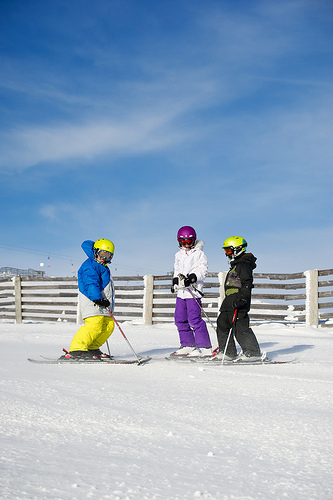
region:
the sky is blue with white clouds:
[14, 7, 332, 251]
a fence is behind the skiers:
[4, 267, 330, 329]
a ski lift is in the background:
[2, 236, 177, 291]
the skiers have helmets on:
[95, 223, 248, 258]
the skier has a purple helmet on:
[170, 224, 199, 250]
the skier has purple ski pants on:
[173, 293, 212, 347]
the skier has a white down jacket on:
[172, 244, 205, 297]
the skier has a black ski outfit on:
[220, 234, 260, 355]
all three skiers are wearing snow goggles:
[90, 235, 238, 265]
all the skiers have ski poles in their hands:
[36, 273, 267, 364]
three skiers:
[76, 230, 276, 359]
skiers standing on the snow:
[90, 233, 283, 371]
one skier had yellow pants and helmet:
[62, 238, 120, 361]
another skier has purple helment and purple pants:
[173, 222, 208, 372]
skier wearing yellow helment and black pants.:
[222, 237, 266, 343]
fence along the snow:
[29, 268, 331, 323]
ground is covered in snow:
[73, 383, 317, 491]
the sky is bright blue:
[75, 23, 295, 142]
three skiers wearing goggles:
[91, 234, 244, 261]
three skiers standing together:
[86, 220, 273, 370]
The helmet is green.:
[216, 232, 258, 260]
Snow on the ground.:
[177, 431, 237, 467]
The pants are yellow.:
[65, 314, 119, 356]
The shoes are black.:
[54, 341, 118, 365]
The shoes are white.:
[174, 342, 211, 359]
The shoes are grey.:
[210, 341, 272, 370]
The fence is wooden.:
[265, 276, 307, 312]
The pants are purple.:
[164, 298, 215, 346]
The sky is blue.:
[6, 16, 63, 46]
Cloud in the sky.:
[32, 132, 94, 161]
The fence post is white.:
[129, 276, 158, 321]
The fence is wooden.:
[27, 286, 54, 310]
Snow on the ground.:
[111, 442, 165, 471]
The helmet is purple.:
[167, 225, 201, 243]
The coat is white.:
[170, 257, 207, 276]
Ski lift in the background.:
[34, 252, 78, 273]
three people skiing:
[27, 226, 291, 367]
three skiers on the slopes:
[24, 206, 304, 397]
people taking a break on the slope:
[24, 192, 280, 395]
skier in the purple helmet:
[160, 218, 217, 364]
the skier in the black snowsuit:
[210, 224, 302, 367]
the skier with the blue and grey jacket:
[23, 214, 154, 377]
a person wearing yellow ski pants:
[21, 220, 159, 385]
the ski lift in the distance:
[1, 235, 172, 277]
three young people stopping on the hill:
[16, 216, 281, 376]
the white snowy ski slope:
[44, 383, 261, 481]